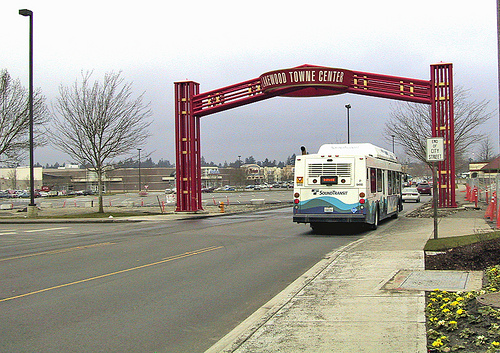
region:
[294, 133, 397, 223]
a white and blue bus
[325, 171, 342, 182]
a sign on the back of the bus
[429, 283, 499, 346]
yellow flowers next to the sidewalk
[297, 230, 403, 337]
the sidewalk next to the bus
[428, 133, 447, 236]
a white street sign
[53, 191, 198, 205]
yellow cones on the ground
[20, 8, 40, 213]
a black lamp post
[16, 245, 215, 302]
yellow lines painted on the street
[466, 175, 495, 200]
a fence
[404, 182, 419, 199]
a car on the street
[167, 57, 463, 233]
A bus is under a red metal archway.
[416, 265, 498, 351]
A patch of yellow and green flowery plants.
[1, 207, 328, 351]
The dark road with a yellow stripe.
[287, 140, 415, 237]
A white and blue bus is stopped.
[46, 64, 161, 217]
A leafless tree in the distance.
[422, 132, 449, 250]
A white sign stands on a patch of grass.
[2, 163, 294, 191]
A long shopping center in the distance.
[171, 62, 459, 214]
A red archway with words in the center.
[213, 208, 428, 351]
A dirty cement sidewalk.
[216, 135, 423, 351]
The bus is parked next to the sidewalk.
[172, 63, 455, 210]
A big red archway in a road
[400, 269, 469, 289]
Sewer or electrical entryway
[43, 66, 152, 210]
A leafless tree outside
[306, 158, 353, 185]
The engine door on a bus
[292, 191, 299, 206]
Pair of tail lights on a bus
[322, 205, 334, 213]
License plate on a bus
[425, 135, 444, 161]
A white street sign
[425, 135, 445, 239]
A street sign on a pole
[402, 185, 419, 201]
A white car on the road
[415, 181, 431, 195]
A red car on the road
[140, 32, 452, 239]
a giant red gate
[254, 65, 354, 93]
the town city logo on a gate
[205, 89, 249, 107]
red bars on a city gate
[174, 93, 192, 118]
yellow decorations on a gate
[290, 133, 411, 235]
a family RV car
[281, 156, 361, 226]
the back of an RV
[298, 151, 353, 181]
the vent of an RV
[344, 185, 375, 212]
the blinkers of an RV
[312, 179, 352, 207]
the logo of an RV car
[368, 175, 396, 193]
the windows of an RV car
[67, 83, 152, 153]
brown bare tree with no leaves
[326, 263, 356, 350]
dirty white area of sidewalk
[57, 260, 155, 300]
yellow line in middle of road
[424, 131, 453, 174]
white street sign on pole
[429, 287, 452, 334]
yellow flowers on right of photo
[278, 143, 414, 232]
white bus with blue waves on back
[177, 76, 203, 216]
red metal side of sign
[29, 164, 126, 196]
large brown building on left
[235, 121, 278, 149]
dark grey area of sky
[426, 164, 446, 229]
silver pole with sign on it